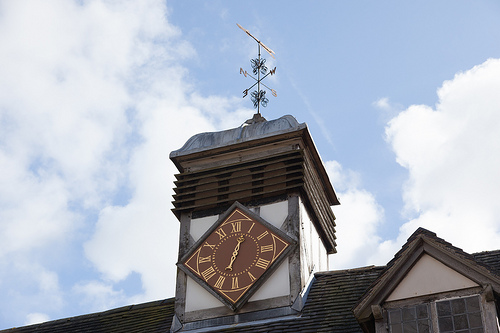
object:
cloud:
[10, 5, 160, 198]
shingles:
[96, 307, 174, 328]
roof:
[0, 225, 499, 332]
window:
[385, 294, 481, 333]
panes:
[385, 295, 486, 332]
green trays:
[175, 200, 299, 314]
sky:
[306, 17, 393, 114]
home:
[350, 227, 500, 333]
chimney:
[168, 113, 341, 333]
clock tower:
[171, 23, 342, 333]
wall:
[407, 271, 455, 290]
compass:
[236, 23, 278, 126]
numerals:
[231, 277, 239, 290]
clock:
[175, 200, 298, 313]